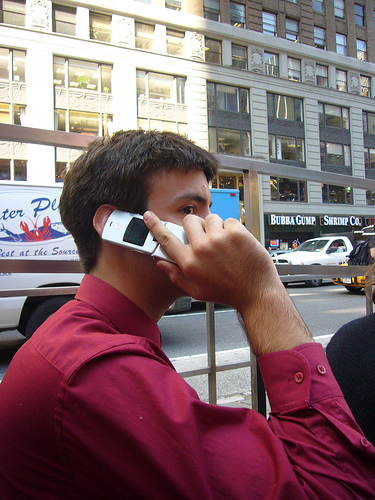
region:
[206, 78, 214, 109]
glass window on building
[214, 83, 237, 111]
glass window on building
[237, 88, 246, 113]
glass window on building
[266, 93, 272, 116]
glass window on building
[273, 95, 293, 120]
glass window on building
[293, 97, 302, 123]
glass window on building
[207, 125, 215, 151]
glass window on building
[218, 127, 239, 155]
glass window on building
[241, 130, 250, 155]
glass window on building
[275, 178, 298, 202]
glass window on building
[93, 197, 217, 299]
Silver flip phone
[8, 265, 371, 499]
Red dress shirt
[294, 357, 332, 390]
Two small red buttons on shirt sleeve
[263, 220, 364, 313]
White truck in the road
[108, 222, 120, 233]
Silver motorola logo on cell phone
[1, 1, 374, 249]
Tall building in the background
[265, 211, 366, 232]
White lettering on store sign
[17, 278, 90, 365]
Black tire on van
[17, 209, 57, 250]
Picture of red lobster on van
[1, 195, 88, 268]
Blue lettering on van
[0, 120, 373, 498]
The man is holding a cell phone.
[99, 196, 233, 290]
The cell phone is silver.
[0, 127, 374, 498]
The man is wearing a long sleeve shirt.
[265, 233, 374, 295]
The truck is white.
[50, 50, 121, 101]
The window is rectangular.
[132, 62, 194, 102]
The window is rectangular.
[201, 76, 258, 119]
The window is rectangular.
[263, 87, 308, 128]
The window is rectangular.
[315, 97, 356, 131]
The window is rectangular.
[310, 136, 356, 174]
The window is rectangular.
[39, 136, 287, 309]
a man on cell phone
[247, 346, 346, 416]
buttons on the sleeve of a red shirt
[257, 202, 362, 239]
bubba gump on sign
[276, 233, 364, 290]
a white truck in the street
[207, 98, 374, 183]
windows over a street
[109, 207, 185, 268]
a silver cell phone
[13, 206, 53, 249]
a lobster on a box truck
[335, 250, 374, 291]
a yellow bumper on a car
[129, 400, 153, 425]
a speck of dirt on shirt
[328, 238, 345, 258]
a man driving a truck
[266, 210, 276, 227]
The letter is white.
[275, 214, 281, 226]
The letter is white.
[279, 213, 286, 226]
The letter is white.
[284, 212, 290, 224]
The letter is white.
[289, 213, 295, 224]
The letter is white.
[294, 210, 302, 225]
The letter is white.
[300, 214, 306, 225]
The letter is white.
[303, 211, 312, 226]
The letter is white.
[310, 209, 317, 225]
The letter is white.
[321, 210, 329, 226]
The letter is white.